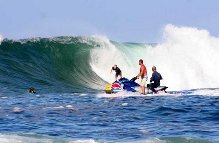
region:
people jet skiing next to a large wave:
[103, 62, 169, 108]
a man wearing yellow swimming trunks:
[136, 57, 145, 94]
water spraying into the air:
[169, 28, 207, 81]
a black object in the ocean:
[29, 83, 37, 96]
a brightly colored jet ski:
[104, 78, 139, 96]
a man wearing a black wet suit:
[107, 61, 125, 76]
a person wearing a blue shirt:
[146, 66, 161, 95]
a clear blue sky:
[46, 6, 173, 32]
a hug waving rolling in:
[30, 33, 112, 81]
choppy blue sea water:
[109, 105, 170, 129]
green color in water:
[71, 96, 134, 130]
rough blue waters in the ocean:
[74, 110, 115, 128]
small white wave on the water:
[116, 100, 135, 110]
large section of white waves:
[163, 25, 209, 84]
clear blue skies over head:
[91, 8, 124, 25]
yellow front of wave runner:
[103, 81, 113, 93]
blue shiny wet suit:
[149, 71, 168, 93]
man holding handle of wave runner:
[128, 72, 151, 88]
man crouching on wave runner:
[107, 62, 124, 81]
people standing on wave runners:
[99, 59, 171, 104]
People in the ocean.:
[103, 55, 173, 100]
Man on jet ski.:
[124, 56, 149, 98]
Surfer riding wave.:
[109, 61, 123, 82]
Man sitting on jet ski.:
[149, 65, 169, 99]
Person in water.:
[24, 84, 39, 96]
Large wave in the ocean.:
[33, 29, 122, 63]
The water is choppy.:
[65, 85, 205, 120]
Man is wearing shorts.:
[136, 57, 147, 95]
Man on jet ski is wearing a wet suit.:
[148, 63, 165, 97]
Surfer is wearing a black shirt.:
[109, 61, 124, 79]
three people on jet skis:
[91, 53, 172, 100]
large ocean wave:
[8, 23, 206, 81]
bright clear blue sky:
[84, 10, 151, 20]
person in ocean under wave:
[20, 75, 52, 99]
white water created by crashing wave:
[172, 29, 208, 74]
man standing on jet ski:
[136, 55, 150, 95]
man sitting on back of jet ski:
[151, 58, 171, 95]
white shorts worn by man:
[137, 71, 149, 89]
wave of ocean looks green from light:
[62, 24, 102, 74]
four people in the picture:
[17, 53, 167, 103]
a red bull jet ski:
[104, 78, 164, 98]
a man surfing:
[108, 61, 127, 81]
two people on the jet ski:
[130, 58, 162, 92]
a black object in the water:
[26, 74, 39, 94]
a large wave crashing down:
[18, 21, 208, 86]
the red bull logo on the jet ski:
[106, 82, 122, 89]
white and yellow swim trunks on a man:
[139, 75, 149, 86]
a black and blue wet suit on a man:
[147, 71, 163, 94]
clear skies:
[8, 3, 217, 32]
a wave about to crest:
[4, 47, 70, 84]